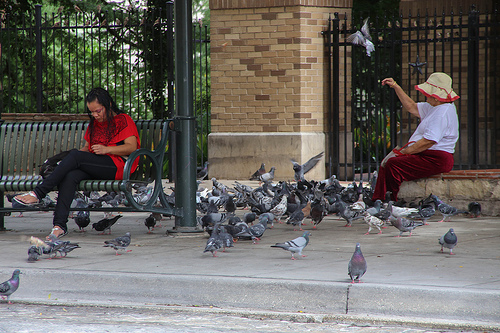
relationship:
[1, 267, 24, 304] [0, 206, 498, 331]
bird on ground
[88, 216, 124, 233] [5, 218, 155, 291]
bird on ground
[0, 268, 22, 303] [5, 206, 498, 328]
bird on sidewalk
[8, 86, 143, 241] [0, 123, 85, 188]
woman on bench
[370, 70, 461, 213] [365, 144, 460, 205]
woman wears bottoms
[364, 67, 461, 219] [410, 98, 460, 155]
woman wears shirt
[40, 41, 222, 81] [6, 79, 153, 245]
fence behind woman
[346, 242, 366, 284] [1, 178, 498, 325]
bird on sidewalk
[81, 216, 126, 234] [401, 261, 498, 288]
bird on ground